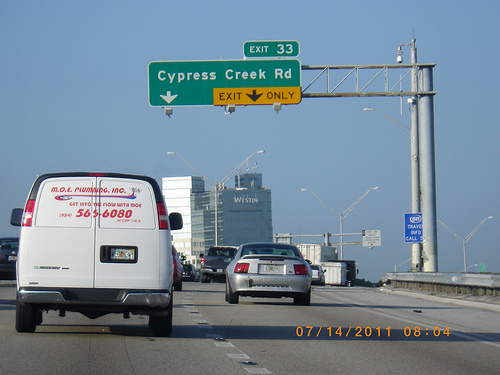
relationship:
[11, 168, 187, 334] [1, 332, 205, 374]
van on top of street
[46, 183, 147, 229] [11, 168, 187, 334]
sign on back of van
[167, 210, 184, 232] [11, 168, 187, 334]
mirror on side of van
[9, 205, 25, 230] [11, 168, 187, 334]
mirror on side of van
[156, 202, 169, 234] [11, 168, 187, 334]
light on back of van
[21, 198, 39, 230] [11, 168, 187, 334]
light on back of van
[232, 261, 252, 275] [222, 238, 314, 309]
light on back of car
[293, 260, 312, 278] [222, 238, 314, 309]
light on back of car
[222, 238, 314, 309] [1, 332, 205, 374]
car on top of street